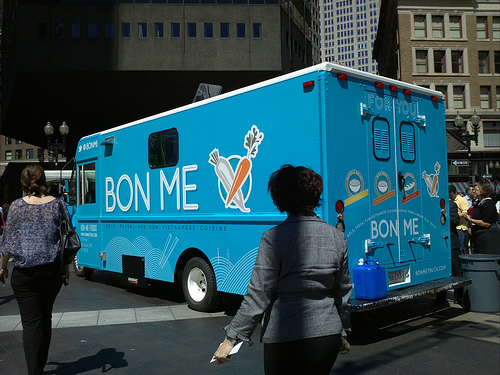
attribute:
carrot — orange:
[226, 124, 265, 211]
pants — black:
[10, 258, 69, 373]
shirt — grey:
[221, 212, 351, 342]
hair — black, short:
[265, 163, 330, 214]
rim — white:
[187, 267, 207, 303]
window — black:
[147, 129, 180, 171]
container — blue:
[351, 256, 388, 303]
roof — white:
[102, 60, 458, 135]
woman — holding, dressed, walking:
[205, 159, 359, 370]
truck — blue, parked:
[57, 60, 473, 330]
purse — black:
[59, 215, 84, 262]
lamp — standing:
[43, 121, 75, 169]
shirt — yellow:
[450, 196, 476, 234]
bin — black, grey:
[460, 251, 499, 316]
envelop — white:
[209, 338, 242, 363]